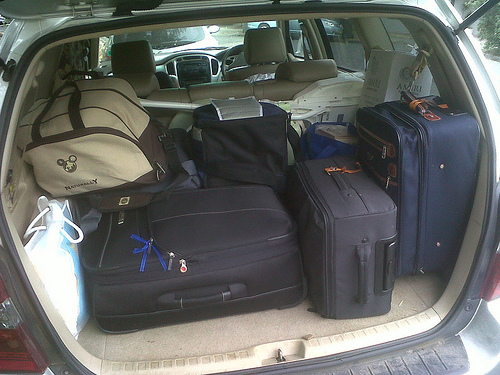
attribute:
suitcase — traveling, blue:
[352, 90, 487, 288]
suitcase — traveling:
[284, 155, 401, 325]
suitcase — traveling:
[68, 178, 310, 338]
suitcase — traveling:
[19, 66, 189, 219]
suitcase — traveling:
[181, 94, 294, 196]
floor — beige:
[73, 271, 454, 362]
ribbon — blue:
[130, 225, 168, 276]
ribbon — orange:
[325, 157, 359, 177]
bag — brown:
[22, 68, 165, 218]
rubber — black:
[286, 330, 471, 374]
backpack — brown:
[18, 63, 175, 207]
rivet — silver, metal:
[438, 162, 443, 171]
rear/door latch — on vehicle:
[274, 343, 288, 365]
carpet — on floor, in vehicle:
[143, 328, 243, 346]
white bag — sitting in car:
[23, 190, 95, 341]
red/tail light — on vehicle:
[0, 285, 40, 373]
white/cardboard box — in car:
[357, 47, 435, 108]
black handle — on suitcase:
[328, 160, 352, 200]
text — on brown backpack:
[55, 175, 100, 192]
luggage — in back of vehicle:
[17, 73, 482, 337]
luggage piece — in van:
[81, 180, 313, 331]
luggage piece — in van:
[295, 147, 401, 319]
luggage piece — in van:
[351, 90, 483, 278]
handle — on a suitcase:
[354, 238, 373, 308]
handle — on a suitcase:
[156, 282, 253, 312]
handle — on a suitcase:
[397, 85, 431, 116]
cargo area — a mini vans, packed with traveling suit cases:
[24, 46, 484, 344]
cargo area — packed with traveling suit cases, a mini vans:
[10, 44, 480, 366]